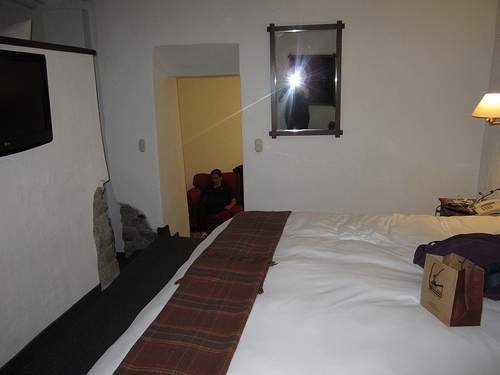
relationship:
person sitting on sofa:
[188, 168, 237, 239] [187, 171, 245, 230]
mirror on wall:
[266, 21, 349, 139] [200, 8, 447, 211]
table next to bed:
[439, 196, 478, 213] [77, 207, 495, 370]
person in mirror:
[281, 69, 313, 127] [274, 25, 335, 131]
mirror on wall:
[266, 20, 346, 140] [100, 6, 497, 219]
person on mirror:
[278, 70, 311, 130] [261, 16, 354, 138]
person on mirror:
[278, 70, 311, 130] [271, 27, 338, 134]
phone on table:
[470, 198, 500, 216] [436, 196, 490, 217]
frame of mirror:
[259, 19, 349, 33] [274, 25, 335, 131]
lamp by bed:
[470, 91, 498, 126] [77, 207, 495, 370]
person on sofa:
[230, 164, 246, 215] [187, 171, 242, 232]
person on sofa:
[194, 167, 234, 229] [187, 171, 242, 232]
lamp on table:
[470, 91, 500, 127] [423, 194, 498, 221]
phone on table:
[470, 194, 497, 221] [423, 194, 498, 221]